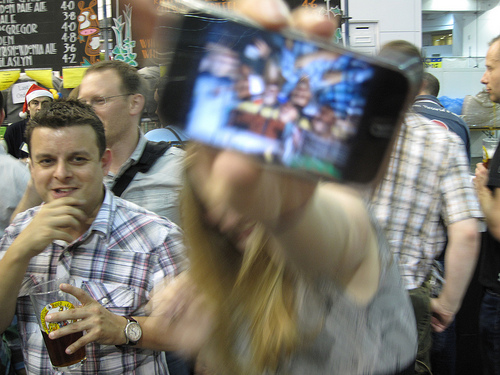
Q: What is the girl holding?
A: A cell phone.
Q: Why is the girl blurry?
A: She is moving.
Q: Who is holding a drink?
A: The guy on the left.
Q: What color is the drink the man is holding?
A: Brown.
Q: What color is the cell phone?
A: Black.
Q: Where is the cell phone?
A: In the girl's hand.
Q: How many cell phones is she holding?
A: 1.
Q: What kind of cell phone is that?
A: An iphone.